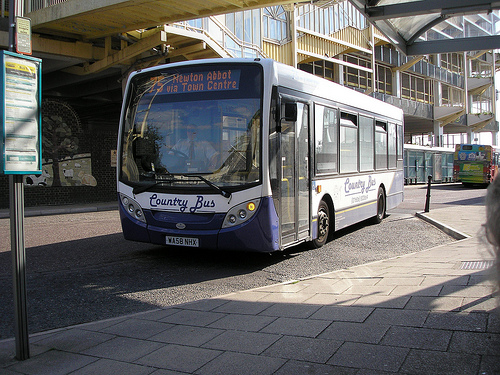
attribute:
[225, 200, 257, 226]
light — in the picture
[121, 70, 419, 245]
bus — in the picture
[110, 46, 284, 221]
windshield — in the picture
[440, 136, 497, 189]
building — in the picture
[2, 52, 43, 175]
sign — in the picture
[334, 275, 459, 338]
curb — in the picture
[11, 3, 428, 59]
walkway — in the picture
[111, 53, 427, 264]
bus — in the picture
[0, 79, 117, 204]
wall — brick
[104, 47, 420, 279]
bus — in the picture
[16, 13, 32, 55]
sticker — in the picture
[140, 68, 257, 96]
destination — in the picture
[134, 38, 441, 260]
bus — in the picture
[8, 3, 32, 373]
post — in the picture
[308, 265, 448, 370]
sidewalk — in the picture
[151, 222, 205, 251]
plate — in the picture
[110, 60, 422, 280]
snow — in the picture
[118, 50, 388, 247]
bus — in the picture